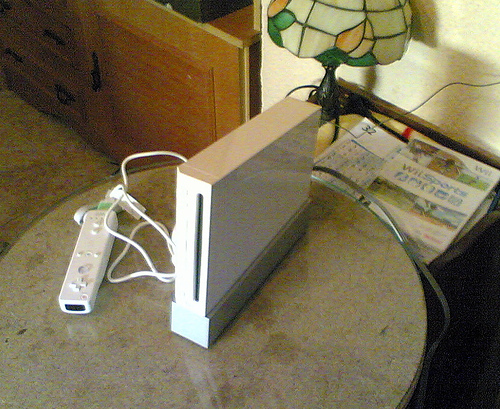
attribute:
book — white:
[359, 136, 499, 263]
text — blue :
[391, 163, 468, 204]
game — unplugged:
[57, 101, 314, 347]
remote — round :
[53, 190, 117, 333]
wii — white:
[171, 96, 322, 350]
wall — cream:
[257, 4, 499, 169]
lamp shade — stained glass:
[264, 3, 424, 78]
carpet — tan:
[0, 109, 132, 247]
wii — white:
[38, 79, 387, 407]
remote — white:
[52, 187, 133, 327]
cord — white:
[85, 130, 193, 315]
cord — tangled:
[106, 134, 186, 306]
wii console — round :
[166, 94, 322, 347]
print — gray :
[396, 161, 425, 188]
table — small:
[5, 130, 440, 407]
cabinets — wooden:
[8, 7, 254, 164]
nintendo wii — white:
[168, 96, 322, 348]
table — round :
[0, 155, 427, 406]